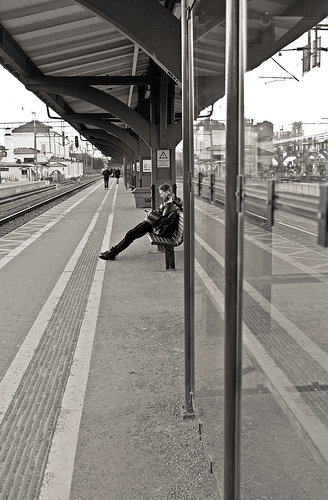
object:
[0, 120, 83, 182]
building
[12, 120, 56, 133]
roof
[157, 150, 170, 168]
sign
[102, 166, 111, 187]
man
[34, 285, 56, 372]
ground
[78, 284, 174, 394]
ground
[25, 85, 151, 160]
metal arches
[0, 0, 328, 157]
roofing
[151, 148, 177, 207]
pillar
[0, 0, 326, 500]
railway station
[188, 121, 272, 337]
reflection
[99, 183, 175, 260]
man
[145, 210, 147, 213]
phone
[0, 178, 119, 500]
line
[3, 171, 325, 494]
ground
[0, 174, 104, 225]
tracks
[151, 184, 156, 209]
post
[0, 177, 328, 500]
platform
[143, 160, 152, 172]
white sign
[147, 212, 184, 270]
bench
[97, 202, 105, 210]
paint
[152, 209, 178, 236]
backpack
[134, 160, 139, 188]
pillar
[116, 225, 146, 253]
legs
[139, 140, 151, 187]
pillar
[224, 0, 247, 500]
pillar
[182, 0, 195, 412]
pillar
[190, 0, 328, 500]
glass